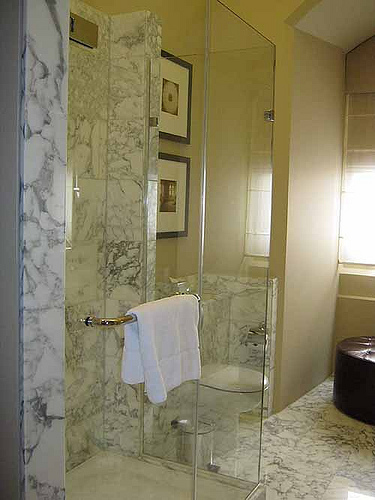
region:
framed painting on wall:
[154, 48, 210, 132]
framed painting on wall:
[147, 167, 181, 229]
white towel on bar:
[114, 305, 198, 403]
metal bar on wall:
[71, 304, 170, 343]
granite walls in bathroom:
[19, 171, 64, 310]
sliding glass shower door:
[158, 110, 244, 379]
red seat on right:
[304, 328, 365, 380]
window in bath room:
[328, 119, 373, 222]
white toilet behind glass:
[176, 356, 268, 420]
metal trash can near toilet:
[150, 407, 211, 458]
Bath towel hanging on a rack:
[122, 294, 201, 405]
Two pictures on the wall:
[155, 49, 193, 240]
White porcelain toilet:
[190, 361, 269, 452]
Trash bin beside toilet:
[174, 413, 214, 470]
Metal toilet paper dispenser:
[246, 326, 268, 349]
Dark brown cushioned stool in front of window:
[332, 334, 374, 426]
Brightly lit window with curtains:
[335, 92, 374, 266]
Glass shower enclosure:
[66, 50, 275, 499]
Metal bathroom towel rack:
[84, 292, 200, 329]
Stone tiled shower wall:
[15, 49, 162, 499]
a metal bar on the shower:
[86, 292, 200, 327]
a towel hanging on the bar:
[120, 294, 200, 404]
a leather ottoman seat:
[332, 334, 374, 425]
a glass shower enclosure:
[64, 0, 274, 499]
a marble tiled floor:
[143, 371, 373, 498]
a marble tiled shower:
[65, 0, 161, 473]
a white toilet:
[177, 362, 268, 449]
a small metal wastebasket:
[170, 415, 220, 472]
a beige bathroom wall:
[278, 29, 346, 412]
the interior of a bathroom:
[0, 0, 374, 499]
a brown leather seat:
[333, 334, 373, 423]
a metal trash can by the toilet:
[176, 419, 221, 471]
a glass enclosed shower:
[74, 0, 272, 499]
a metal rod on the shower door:
[84, 297, 198, 325]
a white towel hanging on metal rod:
[125, 292, 202, 404]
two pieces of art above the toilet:
[159, 53, 193, 236]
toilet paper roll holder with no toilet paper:
[245, 330, 266, 348]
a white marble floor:
[216, 377, 370, 495]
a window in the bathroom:
[341, 93, 372, 268]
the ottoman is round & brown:
[330, 322, 373, 426]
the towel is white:
[107, 289, 209, 402]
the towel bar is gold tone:
[78, 293, 219, 327]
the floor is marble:
[294, 431, 358, 471]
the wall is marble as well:
[43, 105, 118, 318]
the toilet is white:
[196, 358, 274, 426]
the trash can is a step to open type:
[171, 407, 230, 476]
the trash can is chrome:
[171, 403, 237, 475]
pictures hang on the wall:
[157, 46, 205, 247]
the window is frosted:
[339, 155, 369, 246]